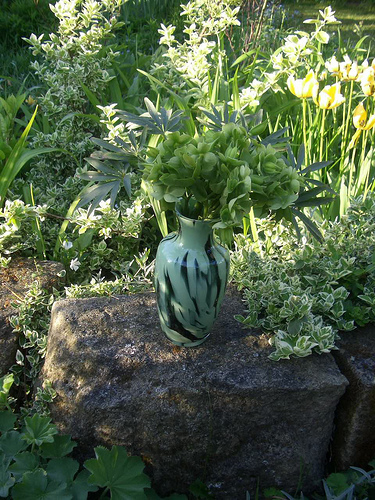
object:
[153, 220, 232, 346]
vase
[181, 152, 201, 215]
plants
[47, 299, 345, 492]
rock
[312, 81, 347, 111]
flowers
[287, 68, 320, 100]
flowers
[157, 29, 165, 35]
leaves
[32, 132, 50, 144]
plants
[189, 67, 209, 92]
plants